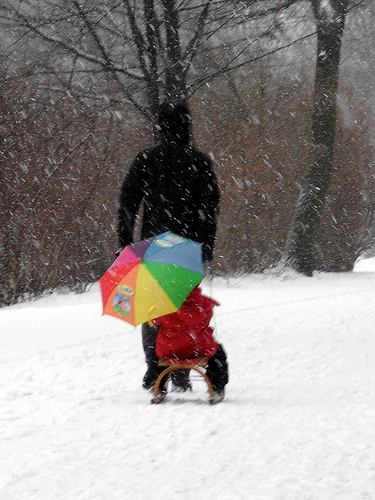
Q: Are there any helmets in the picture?
A: No, there are no helmets.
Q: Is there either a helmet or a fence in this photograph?
A: No, there are no helmets or fences.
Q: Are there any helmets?
A: No, there are no helmets.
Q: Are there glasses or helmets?
A: No, there are no helmets or glasses.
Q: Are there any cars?
A: No, there are no cars.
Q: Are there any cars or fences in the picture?
A: No, there are no cars or fences.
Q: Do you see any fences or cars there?
A: No, there are no cars or fences.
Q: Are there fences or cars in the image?
A: No, there are no cars or fences.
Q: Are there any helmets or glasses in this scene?
A: No, there are no helmets or glasses.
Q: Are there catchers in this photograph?
A: No, there are no catchers.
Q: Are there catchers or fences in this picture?
A: No, there are no catchers or fences.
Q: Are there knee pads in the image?
A: No, there are no knee pads.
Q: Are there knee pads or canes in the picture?
A: No, there are no knee pads or canes.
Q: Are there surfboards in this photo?
A: No, there are no surfboards.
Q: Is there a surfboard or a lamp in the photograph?
A: No, there are no surfboards or lamps.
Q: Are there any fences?
A: No, there are no fences.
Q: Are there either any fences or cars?
A: No, there are no fences or cars.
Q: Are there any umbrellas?
A: Yes, there is an umbrella.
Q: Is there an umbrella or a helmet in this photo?
A: Yes, there is an umbrella.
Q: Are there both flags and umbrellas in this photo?
A: No, there is an umbrella but no flags.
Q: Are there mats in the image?
A: No, there are no mats.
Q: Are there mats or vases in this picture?
A: No, there are no mats or vases.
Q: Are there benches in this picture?
A: Yes, there is a bench.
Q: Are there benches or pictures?
A: Yes, there is a bench.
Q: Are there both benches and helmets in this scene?
A: No, there is a bench but no helmets.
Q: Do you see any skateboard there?
A: No, there are no skateboards.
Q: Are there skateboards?
A: No, there are no skateboards.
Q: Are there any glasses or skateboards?
A: No, there are no skateboards or glasses.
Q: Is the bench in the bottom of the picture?
A: Yes, the bench is in the bottom of the image.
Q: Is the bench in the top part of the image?
A: No, the bench is in the bottom of the image.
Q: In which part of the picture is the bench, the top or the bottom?
A: The bench is in the bottom of the image.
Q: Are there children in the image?
A: Yes, there is a child.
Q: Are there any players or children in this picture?
A: Yes, there is a child.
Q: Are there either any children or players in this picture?
A: Yes, there is a child.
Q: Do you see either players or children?
A: Yes, there is a child.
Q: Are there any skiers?
A: No, there are no skiers.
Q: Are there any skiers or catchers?
A: No, there are no skiers or catchers.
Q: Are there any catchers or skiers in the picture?
A: No, there are no skiers or catchers.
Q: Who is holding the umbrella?
A: The child is holding the umbrella.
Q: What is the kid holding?
A: The kid is holding the umbrella.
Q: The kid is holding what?
A: The kid is holding the umbrella.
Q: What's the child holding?
A: The kid is holding the umbrella.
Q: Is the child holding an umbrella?
A: Yes, the child is holding an umbrella.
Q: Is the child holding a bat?
A: No, the child is holding an umbrella.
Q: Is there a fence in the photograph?
A: No, there are no fences.